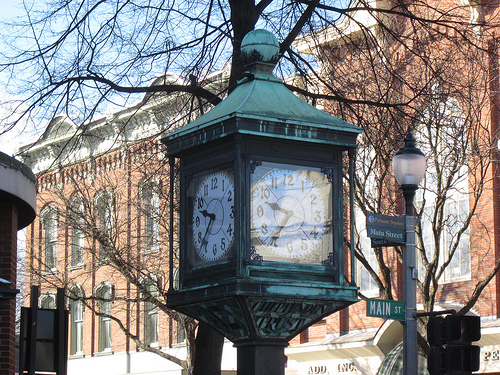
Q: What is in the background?
A: A brown building.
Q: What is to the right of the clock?
A: A light pole.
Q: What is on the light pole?
A: Street signs.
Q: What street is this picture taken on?
A: Main St.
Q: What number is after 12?
A: 1.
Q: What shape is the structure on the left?
A: Curved.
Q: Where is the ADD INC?
A: Background.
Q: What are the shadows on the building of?
A: Trees.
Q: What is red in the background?
A: Brick building.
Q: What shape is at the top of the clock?
A: Sphere.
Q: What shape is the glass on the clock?
A: Square.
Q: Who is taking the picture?
A: A photographer.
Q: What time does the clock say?
A: 9:36.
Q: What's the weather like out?
A: Partly cloudy and cold.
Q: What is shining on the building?
A: The sun.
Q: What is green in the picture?
A: The clock.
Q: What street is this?
A: Main street.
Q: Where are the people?
A: In the buildings.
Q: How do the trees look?
A: Bare.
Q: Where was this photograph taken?
A: Main Street.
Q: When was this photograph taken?
A: 9:36.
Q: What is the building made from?
A: Bricks.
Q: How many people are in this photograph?
A: Zero.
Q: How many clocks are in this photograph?
A: Two.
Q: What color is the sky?
A: Blue.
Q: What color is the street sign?
A: Green.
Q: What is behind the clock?
A: A tree.